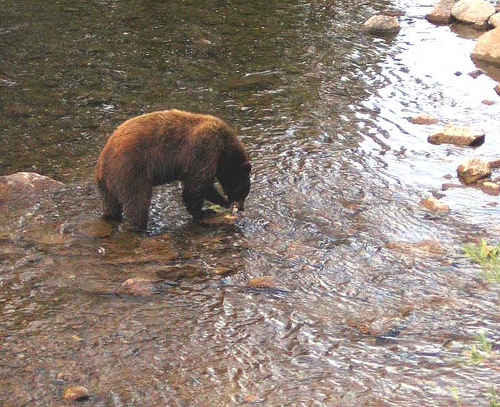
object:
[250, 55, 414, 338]
ripples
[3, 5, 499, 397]
water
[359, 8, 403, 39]
rock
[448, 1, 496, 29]
rock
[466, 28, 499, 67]
rock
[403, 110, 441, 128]
rock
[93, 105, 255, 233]
bear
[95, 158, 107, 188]
tail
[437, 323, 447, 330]
spot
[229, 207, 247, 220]
food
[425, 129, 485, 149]
rock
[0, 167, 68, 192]
rock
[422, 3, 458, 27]
rock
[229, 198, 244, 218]
mouth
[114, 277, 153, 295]
rocks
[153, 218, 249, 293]
reflection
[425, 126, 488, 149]
rocks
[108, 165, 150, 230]
legs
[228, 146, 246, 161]
hair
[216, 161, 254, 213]
head